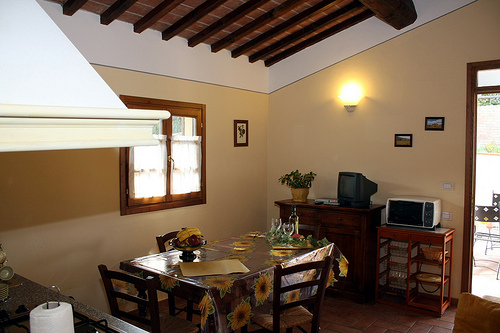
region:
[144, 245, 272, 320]
brown table cloth with sunflowers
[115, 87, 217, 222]
window with brown window frame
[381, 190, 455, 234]
small white microwave oven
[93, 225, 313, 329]
table and three brown chairs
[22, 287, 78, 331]
white paper towel roll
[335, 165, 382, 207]
small black old TV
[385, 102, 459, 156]
two small pictures in frames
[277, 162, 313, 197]
plant in yellow vase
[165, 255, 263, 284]
yellow place mat on table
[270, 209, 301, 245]
two clear wine glasses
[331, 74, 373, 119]
Light on the wall is bright.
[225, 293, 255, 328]
Sunflower on the table cloth.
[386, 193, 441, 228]
toaster oven on the stand.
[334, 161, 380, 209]
A small black televison.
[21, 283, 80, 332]
A roll of paper towels.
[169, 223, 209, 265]
An arrangement of fruit.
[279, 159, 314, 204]
A plant on the stand.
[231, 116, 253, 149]
A picture on the wall.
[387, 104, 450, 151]
A set of two photos.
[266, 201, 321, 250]
A pair of glasses and wine.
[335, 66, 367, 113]
light hanging on wall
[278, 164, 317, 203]
green plant in a tan pot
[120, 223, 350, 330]
table covered with a daisy patterned table cloth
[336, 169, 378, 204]
small black television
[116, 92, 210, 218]
window with a wooden frame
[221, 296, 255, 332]
yellow daisy print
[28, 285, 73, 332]
white paper towel on a silver holder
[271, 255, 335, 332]
brown wooden chair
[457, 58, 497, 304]
door with a brown wooden frame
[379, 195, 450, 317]
white appliance on a red stand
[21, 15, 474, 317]
dining area between kitchen and patio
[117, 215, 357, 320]
tablecloth covered in large sunflowers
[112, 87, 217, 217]
double windows partially covered in curtains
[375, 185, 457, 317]
microwave on top of cart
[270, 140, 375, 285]
television and plant on storage cabinet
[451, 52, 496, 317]
glass door showing outdoor chairs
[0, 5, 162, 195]
large white vent over kitchen counter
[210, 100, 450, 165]
small framed pictures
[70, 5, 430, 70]
dark beams slanted on ceiling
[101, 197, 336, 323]
wooden chairs pushed under table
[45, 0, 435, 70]
Exposed beams on the ceiling.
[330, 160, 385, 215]
A small tv.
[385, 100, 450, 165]
Pictures on the wall.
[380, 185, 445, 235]
A small white toaster oven.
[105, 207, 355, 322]
The tablecloth has pictures of sunflowers on it.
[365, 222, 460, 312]
A small rack and shelves.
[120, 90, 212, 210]
A window with a wood frame.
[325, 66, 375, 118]
A light.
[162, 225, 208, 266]
A bowl of fruit.